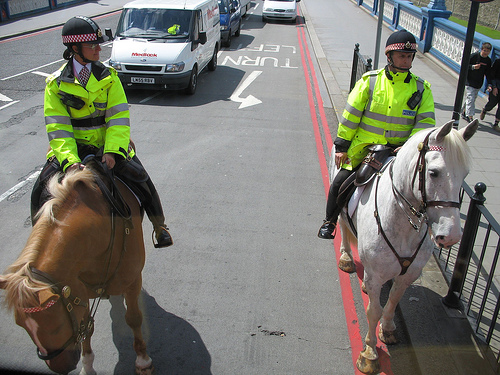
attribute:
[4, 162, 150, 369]
horse — brown, light brown, white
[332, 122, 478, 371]
horse — white, white in color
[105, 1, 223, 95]
van — white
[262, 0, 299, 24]
car — white, small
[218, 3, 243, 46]
car — blue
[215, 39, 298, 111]
traffic directions — painted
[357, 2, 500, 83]
wall — blue, white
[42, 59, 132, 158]
coat — yellow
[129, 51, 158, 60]
writing — red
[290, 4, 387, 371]
stripe — red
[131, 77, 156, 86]
license plate — european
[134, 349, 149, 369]
ankle — white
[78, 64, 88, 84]
tie — checkered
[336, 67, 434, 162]
jacket — bright yellow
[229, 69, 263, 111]
arrow — white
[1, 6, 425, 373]
ground — grey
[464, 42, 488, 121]
person — walking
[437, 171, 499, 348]
guardrail — black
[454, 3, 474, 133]
pole — for lights